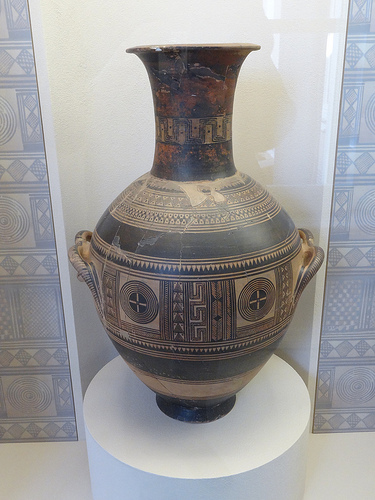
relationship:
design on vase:
[155, 264, 246, 349] [71, 38, 293, 436]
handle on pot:
[275, 224, 327, 307] [66, 37, 327, 426]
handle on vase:
[58, 220, 110, 290] [27, 42, 341, 427]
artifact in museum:
[67, 33, 323, 435] [16, 27, 103, 199]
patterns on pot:
[95, 254, 284, 346] [66, 37, 327, 426]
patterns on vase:
[111, 265, 160, 337] [27, 42, 341, 427]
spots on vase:
[180, 175, 225, 208] [23, 18, 338, 452]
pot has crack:
[66, 37, 327, 426] [98, 214, 121, 289]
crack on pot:
[98, 214, 121, 289] [66, 37, 327, 426]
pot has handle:
[66, 37, 327, 426] [275, 227, 326, 307]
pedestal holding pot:
[77, 353, 314, 498] [66, 37, 327, 426]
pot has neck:
[66, 37, 327, 426] [144, 68, 240, 177]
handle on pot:
[67, 229, 95, 299] [66, 37, 327, 426]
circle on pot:
[234, 275, 279, 324] [66, 37, 327, 426]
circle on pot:
[119, 278, 159, 324] [66, 37, 327, 426]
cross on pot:
[245, 288, 270, 313] [66, 37, 327, 426]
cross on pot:
[122, 287, 151, 316] [66, 37, 327, 426]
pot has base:
[66, 37, 327, 426] [152, 391, 239, 425]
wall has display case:
[0, 0, 362, 443] [25, 0, 354, 499]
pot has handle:
[66, 37, 327, 426] [65, 226, 94, 301]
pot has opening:
[66, 37, 327, 426] [122, 39, 263, 58]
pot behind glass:
[66, 37, 327, 426] [26, 1, 352, 481]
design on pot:
[155, 264, 246, 349] [66, 37, 327, 426]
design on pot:
[234, 276, 280, 325] [66, 37, 327, 426]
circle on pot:
[114, 277, 159, 325] [66, 37, 327, 426]